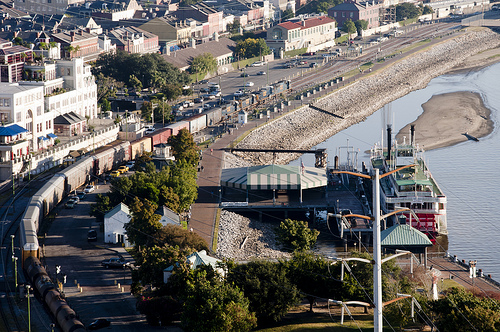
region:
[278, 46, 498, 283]
A large body of water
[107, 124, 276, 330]
Trees are in the foreground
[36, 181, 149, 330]
Trees are casting a shadow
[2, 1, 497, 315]
Photo was taken in the daytime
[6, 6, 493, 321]
Photo was taken outdoors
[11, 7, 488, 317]
The camera angle is pointed down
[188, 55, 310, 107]
Cars are on the street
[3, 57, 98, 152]
Building is white in color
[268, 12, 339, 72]
A building with a red roof in the background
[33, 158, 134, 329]
The road is curved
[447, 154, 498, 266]
The water is clear.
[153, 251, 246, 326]
The trees are lush.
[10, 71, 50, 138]
The building is white.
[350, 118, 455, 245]
The boat is in the water.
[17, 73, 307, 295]
The train is moving.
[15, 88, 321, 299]
The train has many cars.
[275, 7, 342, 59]
The building is large.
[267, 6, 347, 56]
The building has a red roof.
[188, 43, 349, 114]
The parking lot is empty.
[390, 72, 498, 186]
There is a dirt island.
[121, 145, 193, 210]
trees with green leaves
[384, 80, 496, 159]
bare tan island in water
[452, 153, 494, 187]
calm blue water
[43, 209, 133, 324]
shadows of trees on ground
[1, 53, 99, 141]
white building with many windows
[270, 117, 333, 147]
tan gravel next to water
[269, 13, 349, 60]
white house with red roof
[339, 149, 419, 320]
tall electricity pole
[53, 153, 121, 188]
train compartments on a train track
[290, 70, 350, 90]
train track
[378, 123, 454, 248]
A white and red ferry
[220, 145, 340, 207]
The building has a green and white roof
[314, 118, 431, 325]
A grey and orange pole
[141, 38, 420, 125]
Cars parked on the street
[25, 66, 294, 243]
A train on the track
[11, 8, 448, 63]
Houses across the street from the tracks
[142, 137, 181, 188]
A white and black clock tower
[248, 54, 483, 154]
A sloped gravel shore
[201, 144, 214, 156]
A person walking on the sidewalk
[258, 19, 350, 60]
A building with a red roof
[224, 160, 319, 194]
a large green and white umbrella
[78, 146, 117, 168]
a long train passing through a city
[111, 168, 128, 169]
two yellow taxis parked on the street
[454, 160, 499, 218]
a calm blue lake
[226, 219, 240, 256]
gray stone piled on an incline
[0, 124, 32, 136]
a blue awning on a building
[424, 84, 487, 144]
a large sandbar in a lake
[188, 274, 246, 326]
thick green tree tops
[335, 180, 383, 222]
a wooden walkway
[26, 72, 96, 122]
a white building with windows